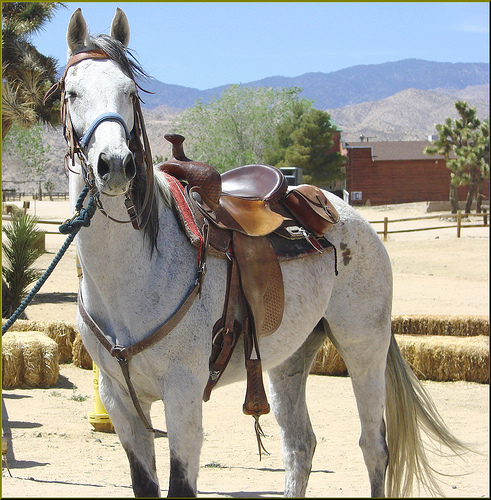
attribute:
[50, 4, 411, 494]
horse — white, here, big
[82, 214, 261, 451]
straps — brown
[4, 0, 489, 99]
sky — blue, clear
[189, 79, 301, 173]
leaves — green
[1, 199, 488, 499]
ground — dirt covered, brown, sandy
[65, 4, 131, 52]
ears — pointed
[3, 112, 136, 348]
rope — blue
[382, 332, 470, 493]
tail — wavy, blonde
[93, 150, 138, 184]
nose — wide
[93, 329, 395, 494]
legs — long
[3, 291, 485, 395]
hay — bailed, well arranged, yellow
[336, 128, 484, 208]
building — red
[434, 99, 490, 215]
tree — green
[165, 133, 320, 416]
saddle — brown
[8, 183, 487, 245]
fence — wooden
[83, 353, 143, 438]
barrel — yellow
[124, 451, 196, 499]
spots — black